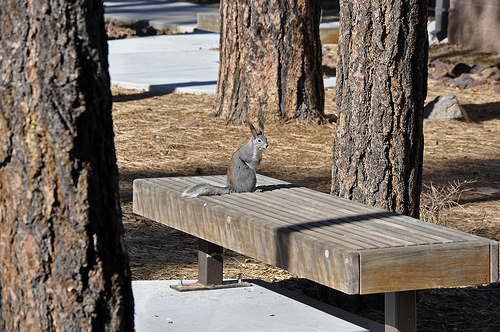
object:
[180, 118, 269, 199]
squirrel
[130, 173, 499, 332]
bench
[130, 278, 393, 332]
sidewalk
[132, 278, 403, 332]
cement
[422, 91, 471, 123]
rock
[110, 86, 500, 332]
ground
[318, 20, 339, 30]
snow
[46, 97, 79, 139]
bark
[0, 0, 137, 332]
tree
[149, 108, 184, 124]
patch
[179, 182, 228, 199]
tail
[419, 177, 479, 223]
weed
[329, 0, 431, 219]
trunk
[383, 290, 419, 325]
support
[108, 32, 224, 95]
cement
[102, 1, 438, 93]
background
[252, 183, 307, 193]
shadow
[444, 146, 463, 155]
straw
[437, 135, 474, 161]
material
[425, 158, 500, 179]
shadow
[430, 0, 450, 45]
pipe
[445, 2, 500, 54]
building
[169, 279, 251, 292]
pad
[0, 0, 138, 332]
trunk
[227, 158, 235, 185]
spot